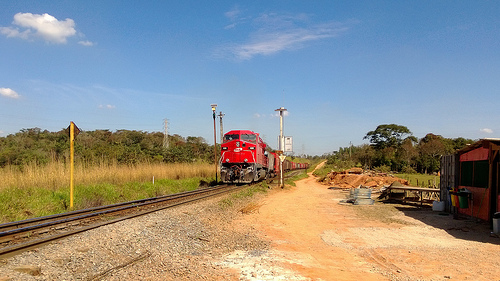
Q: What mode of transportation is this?
A: Train.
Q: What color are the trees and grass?
A: Green.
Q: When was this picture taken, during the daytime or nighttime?
A: Daytime.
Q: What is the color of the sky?
A: Blue.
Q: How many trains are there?
A: One.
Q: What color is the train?
A: Red.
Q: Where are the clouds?
A: The sky.